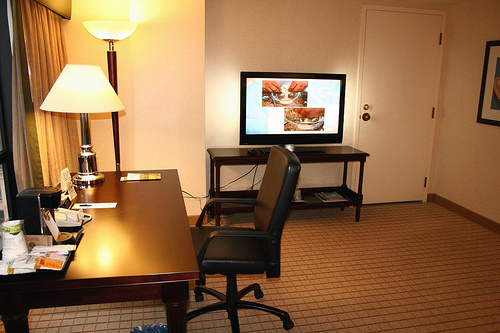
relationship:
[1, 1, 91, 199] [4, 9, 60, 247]
curtains on window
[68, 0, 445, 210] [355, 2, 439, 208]
wall has a door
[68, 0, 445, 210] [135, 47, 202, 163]
wall colored cream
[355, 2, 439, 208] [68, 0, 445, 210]
door in wall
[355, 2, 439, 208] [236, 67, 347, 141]
door next to tv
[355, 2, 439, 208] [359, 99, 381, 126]
door has a lock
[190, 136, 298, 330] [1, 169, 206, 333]
office chair for table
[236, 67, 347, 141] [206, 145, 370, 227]
tv on table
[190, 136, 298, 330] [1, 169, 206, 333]
office chair back from table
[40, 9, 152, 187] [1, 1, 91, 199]
lamps are in front of curtains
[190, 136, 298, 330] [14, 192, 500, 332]
office chair on carpet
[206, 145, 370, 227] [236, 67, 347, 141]
table holds tv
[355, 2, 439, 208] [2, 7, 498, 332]
door in room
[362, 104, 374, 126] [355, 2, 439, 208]
knob on door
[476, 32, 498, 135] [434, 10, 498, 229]
picture hanging on wall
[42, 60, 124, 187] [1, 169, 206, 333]
lamp on table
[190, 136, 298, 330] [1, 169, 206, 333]
office chair near table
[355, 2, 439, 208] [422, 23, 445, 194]
door has hinges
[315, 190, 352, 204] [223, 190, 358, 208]
magazine on shelf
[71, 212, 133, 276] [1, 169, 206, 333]
light reflection on table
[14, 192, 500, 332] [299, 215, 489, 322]
floor patterned with squares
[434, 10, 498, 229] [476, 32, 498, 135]
wall has a picture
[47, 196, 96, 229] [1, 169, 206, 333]
telephone on table